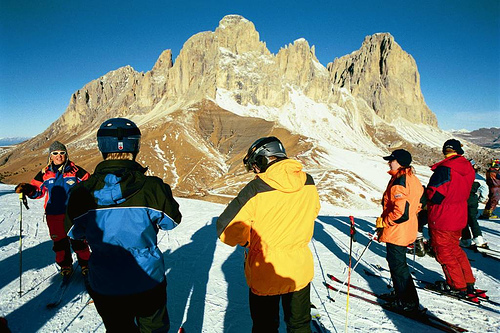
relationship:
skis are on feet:
[319, 272, 442, 326] [378, 281, 423, 313]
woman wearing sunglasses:
[11, 134, 94, 290] [45, 141, 70, 162]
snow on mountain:
[211, 82, 460, 217] [1, 1, 497, 202]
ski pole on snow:
[329, 223, 380, 300] [2, 181, 499, 331]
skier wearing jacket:
[220, 136, 323, 327] [220, 152, 326, 295]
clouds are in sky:
[438, 105, 498, 127] [2, 2, 496, 142]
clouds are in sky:
[4, 107, 499, 150] [2, 2, 496, 142]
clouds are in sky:
[438, 105, 498, 127] [6, 4, 496, 111]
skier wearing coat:
[374, 143, 426, 313] [375, 165, 424, 247]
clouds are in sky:
[0, 116, 39, 138] [2, 2, 496, 142]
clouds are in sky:
[4, 105, 499, 141] [2, 2, 496, 142]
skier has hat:
[375, 149, 428, 321] [381, 137, 413, 167]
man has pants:
[419, 126, 495, 295] [432, 224, 473, 287]